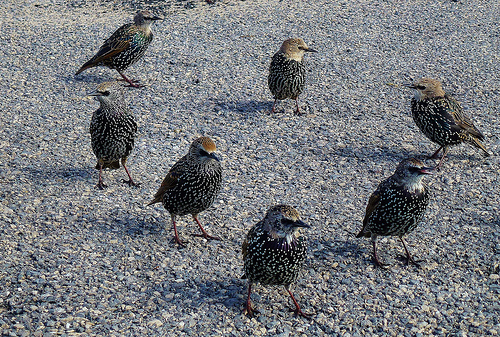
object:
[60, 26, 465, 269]
flock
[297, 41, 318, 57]
black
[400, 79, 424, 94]
black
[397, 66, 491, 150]
bird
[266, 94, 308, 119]
claws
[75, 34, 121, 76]
wing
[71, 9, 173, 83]
bird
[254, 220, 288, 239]
white feathers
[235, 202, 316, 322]
bird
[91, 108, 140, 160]
multicolored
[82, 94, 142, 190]
bird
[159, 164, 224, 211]
talls feathers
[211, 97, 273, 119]
shadow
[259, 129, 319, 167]
pebbles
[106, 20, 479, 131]
little birds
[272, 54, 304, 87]
red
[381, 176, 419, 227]
white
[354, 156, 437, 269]
bird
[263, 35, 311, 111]
bird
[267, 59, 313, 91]
feathers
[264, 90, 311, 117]
black feet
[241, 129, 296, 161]
gravel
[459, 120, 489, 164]
long tail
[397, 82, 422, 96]
sharp black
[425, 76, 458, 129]
brown and white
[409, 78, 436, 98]
birds face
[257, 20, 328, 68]
head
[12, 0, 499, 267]
pavement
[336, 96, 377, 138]
road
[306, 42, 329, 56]
beak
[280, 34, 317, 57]
brown head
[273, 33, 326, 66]
right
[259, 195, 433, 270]
black and white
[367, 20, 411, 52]
rocks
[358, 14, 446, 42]
ground